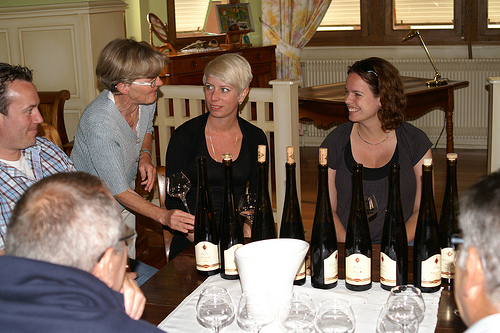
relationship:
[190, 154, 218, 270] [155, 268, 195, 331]
bottle on table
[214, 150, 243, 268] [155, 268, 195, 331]
bottle on table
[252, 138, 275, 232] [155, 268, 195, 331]
bottle on table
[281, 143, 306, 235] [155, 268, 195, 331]
bottle on table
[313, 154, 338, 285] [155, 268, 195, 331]
bottle on table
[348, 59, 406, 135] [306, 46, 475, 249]
hair of woman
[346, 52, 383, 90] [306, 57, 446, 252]
sunglasses on head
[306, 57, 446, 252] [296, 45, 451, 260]
head of woman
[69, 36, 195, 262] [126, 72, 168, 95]
people wearing glasses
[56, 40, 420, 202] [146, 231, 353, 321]
people around table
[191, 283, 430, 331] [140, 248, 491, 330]
glasses on table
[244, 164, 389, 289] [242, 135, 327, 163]
bottles have corks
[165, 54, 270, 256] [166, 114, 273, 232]
lady with shirt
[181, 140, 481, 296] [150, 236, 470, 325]
wine bottles on table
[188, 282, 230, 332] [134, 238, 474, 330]
wine glass on table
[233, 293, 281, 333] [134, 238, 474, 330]
glass on table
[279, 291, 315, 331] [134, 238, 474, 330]
wine glass on table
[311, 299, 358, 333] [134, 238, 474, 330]
glass on table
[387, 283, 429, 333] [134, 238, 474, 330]
glasses on table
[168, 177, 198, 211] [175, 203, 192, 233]
wine glass in hand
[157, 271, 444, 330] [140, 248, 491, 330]
tablecloth on table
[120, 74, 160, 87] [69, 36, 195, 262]
glasses on people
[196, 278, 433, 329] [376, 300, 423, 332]
row of glass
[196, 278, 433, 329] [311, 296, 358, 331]
row of glass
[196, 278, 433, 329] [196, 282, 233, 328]
row of glass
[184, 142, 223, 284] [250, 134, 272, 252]
wine in bottle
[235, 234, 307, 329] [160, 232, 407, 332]
vase in middle table